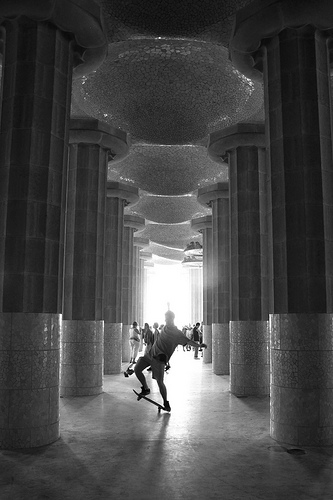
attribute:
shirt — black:
[147, 320, 186, 370]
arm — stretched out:
[176, 333, 209, 352]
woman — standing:
[125, 320, 144, 372]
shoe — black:
[136, 384, 153, 401]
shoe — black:
[159, 396, 173, 411]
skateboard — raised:
[129, 389, 174, 415]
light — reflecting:
[125, 323, 205, 430]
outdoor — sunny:
[144, 249, 191, 332]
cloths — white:
[129, 330, 146, 360]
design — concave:
[72, 34, 255, 136]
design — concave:
[107, 139, 230, 195]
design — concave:
[119, 191, 211, 227]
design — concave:
[138, 221, 200, 246]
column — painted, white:
[0, 2, 77, 457]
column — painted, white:
[57, 141, 111, 397]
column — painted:
[101, 199, 123, 379]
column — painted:
[253, 17, 332, 444]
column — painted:
[222, 147, 272, 399]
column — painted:
[216, 196, 228, 376]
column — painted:
[199, 223, 214, 361]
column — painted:
[122, 231, 132, 373]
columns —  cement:
[180, 21, 332, 485]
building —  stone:
[1, 1, 332, 496]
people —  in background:
[138, 322, 158, 337]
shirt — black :
[151, 326, 188, 369]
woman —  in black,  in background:
[189, 318, 205, 354]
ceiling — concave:
[72, 3, 260, 256]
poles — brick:
[262, 42, 331, 447]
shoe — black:
[164, 402, 171, 411]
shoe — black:
[139, 386, 147, 403]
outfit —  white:
[130, 327, 138, 361]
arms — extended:
[175, 332, 200, 346]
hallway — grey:
[0, 350, 330, 499]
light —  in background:
[143, 259, 204, 327]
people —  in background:
[116, 295, 213, 412]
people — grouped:
[127, 322, 204, 362]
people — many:
[186, 324, 200, 342]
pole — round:
[62, 143, 104, 394]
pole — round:
[224, 144, 271, 395]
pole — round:
[100, 197, 121, 370]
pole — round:
[211, 197, 232, 371]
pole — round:
[121, 225, 136, 362]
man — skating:
[135, 309, 207, 408]